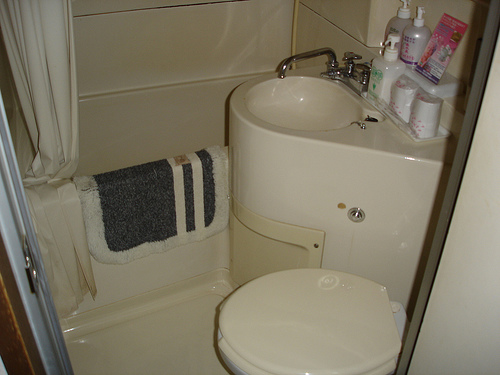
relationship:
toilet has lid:
[201, 265, 409, 372] [214, 266, 404, 369]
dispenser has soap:
[367, 34, 406, 108] [370, 57, 401, 107]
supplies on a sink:
[363, 1, 459, 146] [229, 61, 438, 302]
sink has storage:
[229, 61, 438, 302] [226, 196, 322, 300]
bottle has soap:
[366, 33, 400, 103] [370, 57, 401, 107]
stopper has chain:
[347, 113, 383, 133] [349, 120, 364, 132]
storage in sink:
[226, 196, 322, 300] [229, 61, 438, 302]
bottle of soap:
[366, 33, 400, 103] [370, 57, 401, 107]